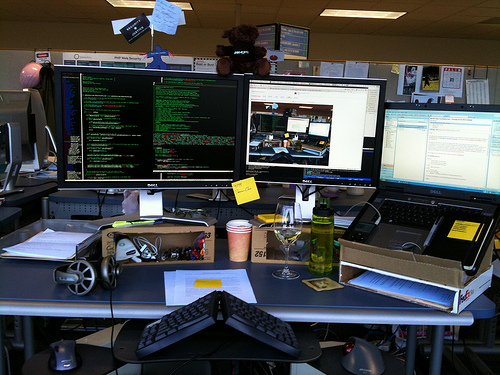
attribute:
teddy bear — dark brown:
[215, 24, 271, 78]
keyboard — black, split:
[157, 281, 287, 356]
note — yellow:
[226, 174, 260, 210]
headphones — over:
[56, 248, 127, 299]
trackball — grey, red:
[337, 336, 371, 370]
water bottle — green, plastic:
[308, 194, 335, 276]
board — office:
[391, 62, 478, 102]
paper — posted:
[441, 66, 461, 95]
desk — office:
[13, 164, 492, 321]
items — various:
[52, 197, 470, 298]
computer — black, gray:
[79, 68, 390, 264]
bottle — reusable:
[304, 197, 346, 275]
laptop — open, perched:
[363, 107, 480, 292]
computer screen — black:
[50, 62, 245, 191]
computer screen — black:
[238, 72, 387, 196]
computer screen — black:
[378, 98, 498, 208]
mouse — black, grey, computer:
[48, 338, 79, 373]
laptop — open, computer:
[340, 98, 499, 267]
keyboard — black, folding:
[132, 283, 302, 361]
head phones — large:
[55, 251, 130, 299]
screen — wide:
[49, 60, 249, 197]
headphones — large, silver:
[58, 244, 138, 301]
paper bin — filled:
[21, 219, 72, 257]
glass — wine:
[273, 201, 303, 281]